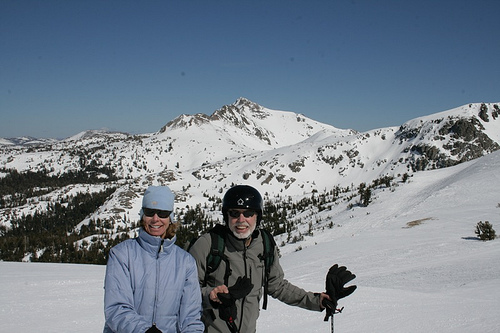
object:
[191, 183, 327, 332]
man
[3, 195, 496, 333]
slope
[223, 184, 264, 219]
helmet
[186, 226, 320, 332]
jacket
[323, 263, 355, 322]
glove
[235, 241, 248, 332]
zipper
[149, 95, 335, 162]
mountain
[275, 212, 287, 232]
tree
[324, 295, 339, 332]
pole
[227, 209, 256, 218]
glasses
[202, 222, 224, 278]
strap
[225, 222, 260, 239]
beard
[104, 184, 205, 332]
woman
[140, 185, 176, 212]
hat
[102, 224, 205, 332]
coat